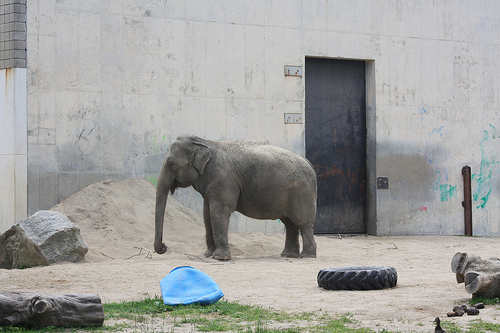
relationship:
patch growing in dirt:
[0, 294, 375, 333] [246, 261, 364, 314]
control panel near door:
[377, 176, 389, 190] [306, 56, 368, 236]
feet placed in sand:
[203, 245, 233, 263] [0, 236, 499, 333]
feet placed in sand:
[299, 247, 317, 259] [0, 236, 499, 333]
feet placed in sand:
[203, 245, 216, 257] [0, 236, 499, 333]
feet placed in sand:
[279, 247, 322, 257] [0, 236, 499, 333]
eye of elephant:
[168, 159, 176, 169] [153, 135, 320, 261]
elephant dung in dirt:
[466, 307, 481, 316] [0, 236, 499, 333]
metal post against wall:
[462, 166, 474, 236] [0, 0, 500, 238]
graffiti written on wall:
[436, 124, 497, 211] [0, 0, 500, 238]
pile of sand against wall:
[50, 174, 206, 257] [0, 0, 500, 238]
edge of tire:
[326, 271, 386, 287] [317, 265, 400, 289]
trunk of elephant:
[154, 167, 174, 255] [153, 135, 320, 261]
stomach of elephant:
[237, 184, 283, 221] [153, 135, 320, 261]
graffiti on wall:
[436, 124, 497, 211] [0, 0, 500, 238]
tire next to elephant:
[317, 265, 400, 289] [153, 135, 320, 261]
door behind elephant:
[306, 56, 368, 236] [153, 135, 320, 261]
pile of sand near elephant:
[50, 174, 206, 257] [153, 135, 320, 261]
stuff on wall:
[414, 105, 449, 181] [0, 0, 500, 238]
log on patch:
[0, 290, 107, 328] [0, 294, 375, 333]